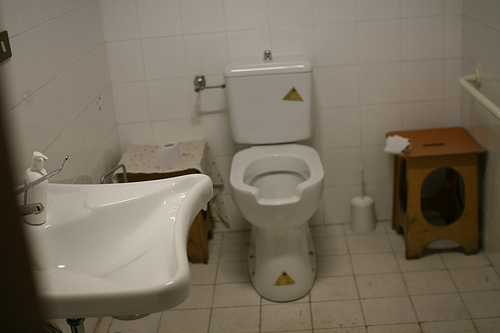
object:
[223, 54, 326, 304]
toilet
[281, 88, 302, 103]
sticker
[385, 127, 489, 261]
stool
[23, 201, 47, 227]
dispenser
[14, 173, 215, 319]
sink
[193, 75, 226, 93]
pipe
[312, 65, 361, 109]
tile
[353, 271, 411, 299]
floor tile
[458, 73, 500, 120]
handrail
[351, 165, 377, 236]
toilet cleaner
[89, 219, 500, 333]
floor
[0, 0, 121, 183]
wall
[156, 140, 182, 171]
toilet paper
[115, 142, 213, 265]
stool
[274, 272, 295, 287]
sticker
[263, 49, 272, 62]
button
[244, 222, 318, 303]
base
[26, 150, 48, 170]
faucet